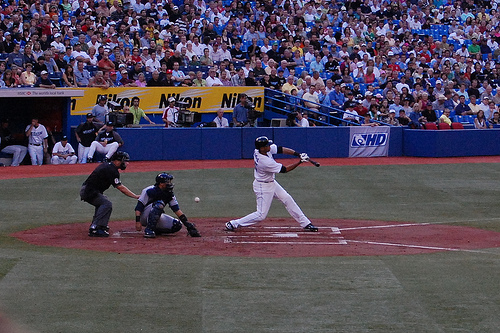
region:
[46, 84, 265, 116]
n nikon nikon nikon on bright yellow banner in the stands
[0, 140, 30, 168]
a pair of legs w/ bent knees in dugout belonging to elsewise invisible man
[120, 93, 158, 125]
man in lime green shirt in front of nikon banner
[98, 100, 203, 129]
two large video cameras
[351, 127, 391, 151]
royal blue 'hd' on small square bluegrey banner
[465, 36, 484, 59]
man in stands wears short sleeve kelly green shirt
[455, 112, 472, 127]
empty seat, front row, in stands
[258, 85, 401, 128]
three blue metal bleacher rails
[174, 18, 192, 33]
person in stands wears 'prison outfit' black+white striped shirt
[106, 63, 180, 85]
two people in stands, one a kid, wear red baseball caps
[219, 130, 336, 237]
baseball player with bat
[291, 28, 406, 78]
baseball spectators in stands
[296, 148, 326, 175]
bat in hand of player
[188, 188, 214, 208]
baseball in the air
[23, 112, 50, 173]
player standing in dugout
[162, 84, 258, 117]
name of sponsor on banner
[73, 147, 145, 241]
umpire crouched in dirt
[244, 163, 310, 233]
white uniform on player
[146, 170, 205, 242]
catcher with mitt on ground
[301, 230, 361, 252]
white lines in dirt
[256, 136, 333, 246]
batter missed the ball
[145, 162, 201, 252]
catcher waiting for ball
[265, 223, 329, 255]
homeplate is white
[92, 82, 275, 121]
Nikon sign is yellow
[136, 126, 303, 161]
baseball wall is blue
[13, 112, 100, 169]
players in the dugout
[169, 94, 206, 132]
man is taking pictures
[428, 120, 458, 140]
three empty stadium seats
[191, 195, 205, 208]
the baseball is white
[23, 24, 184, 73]
fans are in the stadium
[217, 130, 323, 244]
a baseball player swinging a bat.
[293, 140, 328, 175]
a bat on a baseball players hands.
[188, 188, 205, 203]
a baseball flying through the air.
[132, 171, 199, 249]
a catcher standing behind a hitter.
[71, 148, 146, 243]
a man kneeling down.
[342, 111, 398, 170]
a sign in the crowd advertising.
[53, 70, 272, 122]
a yellow and black nikon sign.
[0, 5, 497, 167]
an audience at a baseball game.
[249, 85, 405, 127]
blue metal hand rails.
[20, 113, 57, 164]
a baseball player standing in a dugout.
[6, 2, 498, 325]
Outdoor scene, featuring man-made facility.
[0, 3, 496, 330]
Stadium and baseball field with players.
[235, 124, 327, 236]
Batter in motion.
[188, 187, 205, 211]
Ball, headed for catcher.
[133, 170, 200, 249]
Crouched catcher.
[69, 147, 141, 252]
Umpire, standing, knees bent, hand leaning on catcher.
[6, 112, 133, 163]
Watching players in dugout.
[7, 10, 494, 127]
Packed to capactiy stadiium.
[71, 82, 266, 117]
Yellow advertisement for Nikon.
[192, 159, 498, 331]
Home plate, surrounded by field.